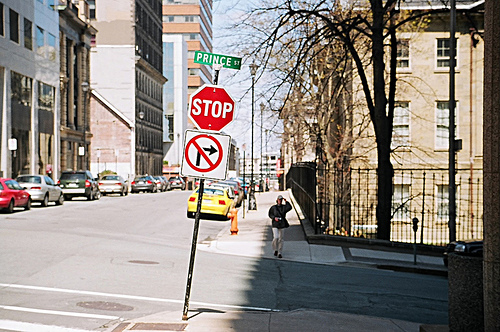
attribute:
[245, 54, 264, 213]
pole — tall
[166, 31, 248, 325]
leaning pole — metal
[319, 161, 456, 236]
fence — black, iron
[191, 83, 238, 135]
sign — red, white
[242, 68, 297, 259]
light — tall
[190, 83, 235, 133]
sign — red, stop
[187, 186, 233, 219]
car — yellow, parked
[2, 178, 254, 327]
street — weathered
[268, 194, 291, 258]
person — walking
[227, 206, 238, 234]
hydrant — orange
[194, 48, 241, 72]
sign — green, street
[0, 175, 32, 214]
car — red, parked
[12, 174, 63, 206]
car — silver, parked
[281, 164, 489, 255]
fence — black, metal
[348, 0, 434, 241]
tree — bare, tall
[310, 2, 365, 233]
tree — bare, tall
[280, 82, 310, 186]
tree — bare, tall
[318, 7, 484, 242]
building — tan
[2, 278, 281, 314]
line — white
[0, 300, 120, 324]
line — white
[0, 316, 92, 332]
line — white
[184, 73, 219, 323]
pole — metal, slanting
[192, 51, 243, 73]
sign — road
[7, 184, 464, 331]
asphalt — grey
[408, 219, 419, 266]
meter — parking